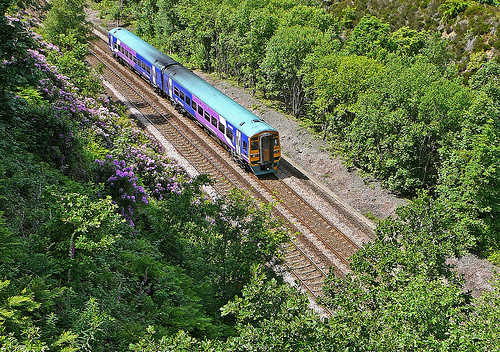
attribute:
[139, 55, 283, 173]
train — blue, purple, traveling, colorful, light, turqoise, yellow, glass, here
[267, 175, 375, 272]
track — empty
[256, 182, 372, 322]
tracks — unused, set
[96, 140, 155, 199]
flower — purple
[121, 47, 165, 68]
windows — along, glass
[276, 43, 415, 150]
trees — lining, along, growing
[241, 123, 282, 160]
front — yellow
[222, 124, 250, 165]
doors — white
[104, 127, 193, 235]
flowers — pink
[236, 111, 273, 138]
marks — black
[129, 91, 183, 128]
shadow — cast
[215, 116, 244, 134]
window — glass